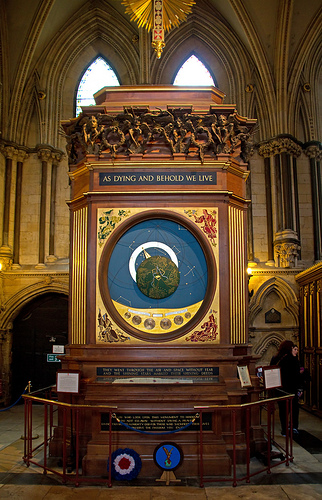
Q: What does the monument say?
A: As dying and behold we live.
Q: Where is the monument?
A: Museum.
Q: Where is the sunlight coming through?
A: Windows.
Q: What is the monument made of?
A: Wood.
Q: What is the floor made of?
A: Tile.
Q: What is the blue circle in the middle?
A: Space.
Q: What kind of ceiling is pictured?
A: Cathedral.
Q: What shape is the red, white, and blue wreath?
A: Round.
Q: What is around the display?
A: Railing.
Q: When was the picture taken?
A: During the day.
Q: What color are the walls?
A: Brown.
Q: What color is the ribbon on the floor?
A: Red, white and blue.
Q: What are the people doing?
A: Viewing the monument.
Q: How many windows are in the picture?
A: Two.